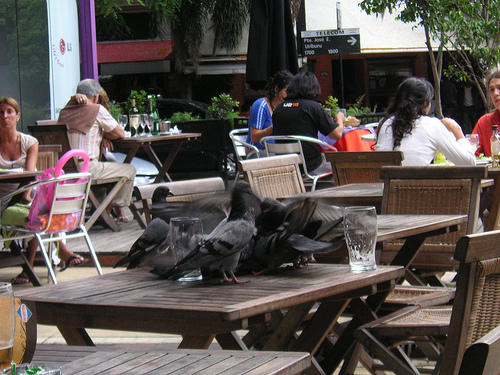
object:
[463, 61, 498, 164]
person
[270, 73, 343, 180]
person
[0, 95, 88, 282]
person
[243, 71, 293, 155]
person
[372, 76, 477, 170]
person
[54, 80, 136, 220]
person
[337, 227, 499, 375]
chair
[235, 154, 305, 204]
chair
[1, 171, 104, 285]
chair